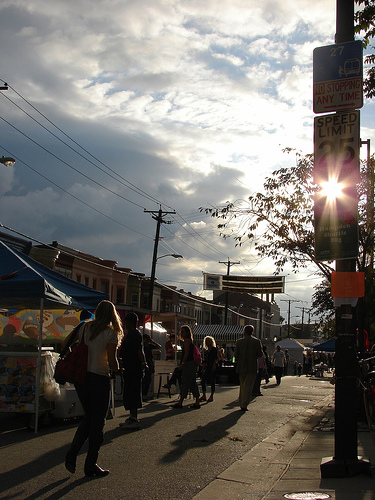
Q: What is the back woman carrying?
A: A bag.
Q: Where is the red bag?
A: Over the woman's shoulder.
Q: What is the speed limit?
A: 25.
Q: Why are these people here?
A: To buy items.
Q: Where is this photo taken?
A: Street market.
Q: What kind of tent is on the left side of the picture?
A: Blue pop up tent.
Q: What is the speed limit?
A: 25 MPH.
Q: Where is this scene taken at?
A: City.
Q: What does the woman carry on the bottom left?
A: Large bag.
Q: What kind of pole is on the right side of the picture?
A: Black street pole.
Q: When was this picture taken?
A: Sunset.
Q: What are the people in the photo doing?
A: Walking.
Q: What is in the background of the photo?
A: Buildings.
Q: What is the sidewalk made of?
A: Cement.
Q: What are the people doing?
A: Walking.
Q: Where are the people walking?
A: On paved road.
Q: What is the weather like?
A: Cloudy and sunny.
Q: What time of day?
A: Right before sunset.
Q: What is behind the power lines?
A: Buildings.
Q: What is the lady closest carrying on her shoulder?
A: Purse.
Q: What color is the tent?
A: Blue.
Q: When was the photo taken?
A: During the daytime.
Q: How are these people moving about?
A: Walking.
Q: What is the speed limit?
A: 25.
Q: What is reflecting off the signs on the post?
A: Sunshine.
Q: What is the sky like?
A: Mostly cloudy.